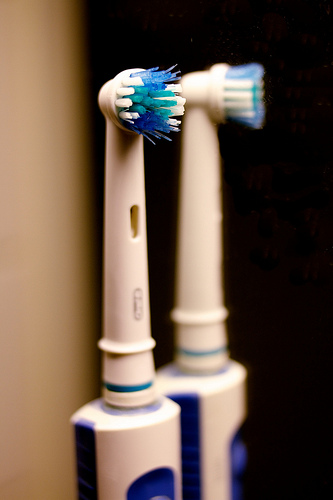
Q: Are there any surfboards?
A: No, there are no surfboards.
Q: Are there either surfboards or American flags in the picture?
A: No, there are no surfboards or American flags.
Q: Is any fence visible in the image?
A: No, there are no fences.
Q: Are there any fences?
A: No, there are no fences.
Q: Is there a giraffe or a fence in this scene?
A: No, there are no fences or giraffes.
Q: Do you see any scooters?
A: No, there are no scooters.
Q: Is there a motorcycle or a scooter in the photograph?
A: No, there are no scooters or motorcycles.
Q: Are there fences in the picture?
A: No, there are no fences.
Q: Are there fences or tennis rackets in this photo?
A: No, there are no fences or tennis rackets.